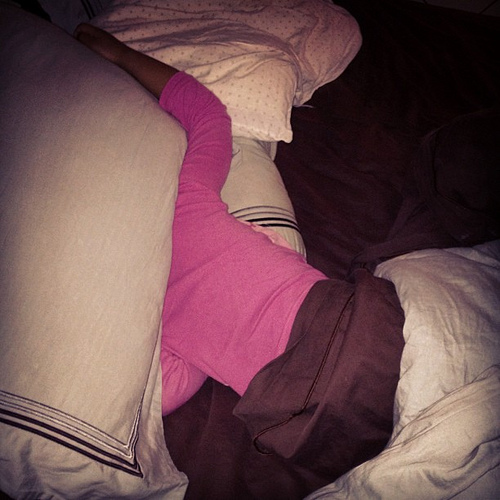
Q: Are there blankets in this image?
A: Yes, there is a blanket.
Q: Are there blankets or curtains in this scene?
A: Yes, there is a blanket.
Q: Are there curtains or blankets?
A: Yes, there is a blanket.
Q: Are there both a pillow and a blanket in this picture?
A: Yes, there are both a blanket and a pillow.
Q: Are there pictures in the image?
A: No, there are no pictures.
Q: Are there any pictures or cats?
A: No, there are no pictures or cats.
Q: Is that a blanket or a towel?
A: That is a blanket.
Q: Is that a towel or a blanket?
A: That is a blanket.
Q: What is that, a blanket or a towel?
A: That is a blanket.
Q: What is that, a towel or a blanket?
A: That is a blanket.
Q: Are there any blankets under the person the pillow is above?
A: Yes, there is a blanket under the person.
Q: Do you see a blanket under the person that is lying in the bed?
A: Yes, there is a blanket under the person.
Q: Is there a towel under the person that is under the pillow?
A: No, there is a blanket under the person.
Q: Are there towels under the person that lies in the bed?
A: No, there is a blanket under the person.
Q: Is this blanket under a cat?
A: No, the blanket is under a person.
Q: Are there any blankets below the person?
A: Yes, there is a blanket below the person.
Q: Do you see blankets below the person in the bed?
A: Yes, there is a blanket below the person.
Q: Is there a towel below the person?
A: No, there is a blanket below the person.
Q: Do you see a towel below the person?
A: No, there is a blanket below the person.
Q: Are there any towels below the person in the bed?
A: No, there is a blanket below the person.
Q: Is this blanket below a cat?
A: No, the blanket is below the person.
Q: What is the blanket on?
A: The blanket is on the bed.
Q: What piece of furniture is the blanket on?
A: The blanket is on the bed.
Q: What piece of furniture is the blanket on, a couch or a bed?
A: The blanket is on a bed.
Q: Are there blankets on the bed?
A: Yes, there is a blanket on the bed.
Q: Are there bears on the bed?
A: No, there is a blanket on the bed.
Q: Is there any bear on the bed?
A: No, there is a blanket on the bed.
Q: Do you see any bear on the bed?
A: No, there is a blanket on the bed.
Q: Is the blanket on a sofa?
A: No, the blanket is on a bed.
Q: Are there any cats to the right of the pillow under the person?
A: No, there is a blanket to the right of the pillow.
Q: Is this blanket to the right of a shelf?
A: No, the blanket is to the right of a pillow.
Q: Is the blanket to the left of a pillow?
A: No, the blanket is to the right of a pillow.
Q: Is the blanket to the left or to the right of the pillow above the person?
A: The blanket is to the right of the pillow.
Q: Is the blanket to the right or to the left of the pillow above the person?
A: The blanket is to the right of the pillow.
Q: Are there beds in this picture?
A: Yes, there is a bed.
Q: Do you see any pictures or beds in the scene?
A: Yes, there is a bed.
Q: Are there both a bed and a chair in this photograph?
A: No, there is a bed but no chairs.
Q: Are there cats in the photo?
A: No, there are no cats.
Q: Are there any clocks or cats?
A: No, there are no cats or clocks.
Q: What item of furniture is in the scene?
A: The piece of furniture is a bed.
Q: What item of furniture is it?
A: The piece of furniture is a bed.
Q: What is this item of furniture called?
A: This is a bed.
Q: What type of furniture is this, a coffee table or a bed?
A: This is a bed.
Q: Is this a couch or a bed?
A: This is a bed.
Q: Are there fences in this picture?
A: No, there are no fences.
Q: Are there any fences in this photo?
A: No, there are no fences.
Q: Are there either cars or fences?
A: No, there are no fences or cars.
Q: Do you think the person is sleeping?
A: Yes, the person is sleeping.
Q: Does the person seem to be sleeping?
A: Yes, the person is sleeping.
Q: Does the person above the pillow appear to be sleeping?
A: Yes, the person is sleeping.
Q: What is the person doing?
A: The person is sleeping.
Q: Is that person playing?
A: No, the person is sleeping.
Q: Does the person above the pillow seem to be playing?
A: No, the person is sleeping.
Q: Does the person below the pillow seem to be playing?
A: No, the person is sleeping.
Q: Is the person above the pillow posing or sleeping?
A: The person is sleeping.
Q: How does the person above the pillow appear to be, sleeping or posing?
A: The person is sleeping.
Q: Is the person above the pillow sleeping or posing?
A: The person is sleeping.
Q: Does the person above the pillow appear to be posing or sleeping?
A: The person is sleeping.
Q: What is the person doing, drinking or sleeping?
A: The person is sleeping.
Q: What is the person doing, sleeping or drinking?
A: The person is sleeping.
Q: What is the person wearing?
A: The person is wearing a shirt.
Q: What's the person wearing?
A: The person is wearing a shirt.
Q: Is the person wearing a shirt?
A: Yes, the person is wearing a shirt.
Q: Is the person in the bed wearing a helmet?
A: No, the person is wearing a shirt.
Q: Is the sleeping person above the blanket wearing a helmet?
A: No, the person is wearing a shirt.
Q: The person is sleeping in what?
A: The person is sleeping in the bed.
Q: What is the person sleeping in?
A: The person is sleeping in the bed.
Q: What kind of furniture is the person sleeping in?
A: The person is sleeping in the bed.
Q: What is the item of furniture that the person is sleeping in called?
A: The piece of furniture is a bed.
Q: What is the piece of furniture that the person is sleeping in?
A: The piece of furniture is a bed.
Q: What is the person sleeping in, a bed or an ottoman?
A: The person is sleeping in a bed.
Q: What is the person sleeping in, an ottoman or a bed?
A: The person is sleeping in a bed.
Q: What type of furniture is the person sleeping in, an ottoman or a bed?
A: The person is sleeping in a bed.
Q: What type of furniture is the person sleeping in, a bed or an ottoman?
A: The person is sleeping in a bed.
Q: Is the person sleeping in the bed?
A: Yes, the person is sleeping in the bed.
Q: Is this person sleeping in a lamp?
A: No, the person is sleeping in the bed.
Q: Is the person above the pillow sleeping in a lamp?
A: No, the person is sleeping in the bed.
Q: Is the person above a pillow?
A: Yes, the person is above a pillow.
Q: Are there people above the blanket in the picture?
A: Yes, there is a person above the blanket.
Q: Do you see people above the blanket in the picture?
A: Yes, there is a person above the blanket.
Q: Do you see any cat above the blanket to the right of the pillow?
A: No, there is a person above the blanket.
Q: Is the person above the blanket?
A: Yes, the person is above the blanket.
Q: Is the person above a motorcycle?
A: No, the person is above the blanket.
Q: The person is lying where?
A: The person is lying in the bed.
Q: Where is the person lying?
A: The person is lying in the bed.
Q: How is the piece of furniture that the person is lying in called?
A: The piece of furniture is a bed.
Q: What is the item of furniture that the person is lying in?
A: The piece of furniture is a bed.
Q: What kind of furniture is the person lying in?
A: The person is lying in the bed.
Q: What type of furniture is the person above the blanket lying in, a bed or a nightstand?
A: The person is lying in a bed.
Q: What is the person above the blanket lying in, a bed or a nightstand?
A: The person is lying in a bed.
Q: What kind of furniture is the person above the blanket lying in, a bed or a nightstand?
A: The person is lying in a bed.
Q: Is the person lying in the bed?
A: Yes, the person is lying in the bed.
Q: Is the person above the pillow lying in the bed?
A: Yes, the person is lying in the bed.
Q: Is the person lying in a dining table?
A: No, the person is lying in the bed.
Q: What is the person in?
A: The person is in the bed.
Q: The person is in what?
A: The person is in the bed.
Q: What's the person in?
A: The person is in the bed.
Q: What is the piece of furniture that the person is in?
A: The piece of furniture is a bed.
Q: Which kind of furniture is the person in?
A: The person is in the bed.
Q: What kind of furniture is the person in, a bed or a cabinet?
A: The person is in a bed.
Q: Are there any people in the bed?
A: Yes, there is a person in the bed.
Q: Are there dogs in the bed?
A: No, there is a person in the bed.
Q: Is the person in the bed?
A: Yes, the person is in the bed.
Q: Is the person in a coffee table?
A: No, the person is in the bed.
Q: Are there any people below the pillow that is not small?
A: Yes, there is a person below the pillow.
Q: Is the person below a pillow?
A: Yes, the person is below a pillow.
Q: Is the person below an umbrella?
A: No, the person is below a pillow.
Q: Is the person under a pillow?
A: Yes, the person is under a pillow.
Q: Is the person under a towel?
A: No, the person is under a pillow.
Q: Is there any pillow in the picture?
A: Yes, there is a pillow.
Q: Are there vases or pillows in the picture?
A: Yes, there is a pillow.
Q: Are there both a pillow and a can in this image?
A: No, there is a pillow but no cans.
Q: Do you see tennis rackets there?
A: No, there are no tennis rackets.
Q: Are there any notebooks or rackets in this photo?
A: No, there are no rackets or notebooks.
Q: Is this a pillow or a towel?
A: This is a pillow.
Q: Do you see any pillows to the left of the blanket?
A: Yes, there is a pillow to the left of the blanket.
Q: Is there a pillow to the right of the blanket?
A: No, the pillow is to the left of the blanket.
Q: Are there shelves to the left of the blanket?
A: No, there is a pillow to the left of the blanket.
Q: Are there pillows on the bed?
A: Yes, there is a pillow on the bed.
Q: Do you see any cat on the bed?
A: No, there is a pillow on the bed.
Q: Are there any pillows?
A: Yes, there is a pillow.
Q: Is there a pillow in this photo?
A: Yes, there is a pillow.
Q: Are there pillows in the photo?
A: Yes, there is a pillow.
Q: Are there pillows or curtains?
A: Yes, there is a pillow.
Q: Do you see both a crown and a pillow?
A: No, there is a pillow but no crowns.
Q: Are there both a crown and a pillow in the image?
A: No, there is a pillow but no crowns.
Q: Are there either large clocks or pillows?
A: Yes, there is a large pillow.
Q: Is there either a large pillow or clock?
A: Yes, there is a large pillow.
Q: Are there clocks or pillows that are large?
A: Yes, the pillow is large.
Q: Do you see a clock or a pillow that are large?
A: Yes, the pillow is large.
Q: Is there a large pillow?
A: Yes, there is a large pillow.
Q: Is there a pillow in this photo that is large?
A: Yes, there is a pillow that is large.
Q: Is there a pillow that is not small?
A: Yes, there is a large pillow.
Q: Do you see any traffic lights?
A: No, there are no traffic lights.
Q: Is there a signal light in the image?
A: No, there are no traffic lights.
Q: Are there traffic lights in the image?
A: No, there are no traffic lights.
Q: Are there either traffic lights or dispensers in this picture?
A: No, there are no traffic lights or dispensers.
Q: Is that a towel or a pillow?
A: That is a pillow.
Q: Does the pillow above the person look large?
A: Yes, the pillow is large.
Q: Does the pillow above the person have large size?
A: Yes, the pillow is large.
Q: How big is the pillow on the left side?
A: The pillow is large.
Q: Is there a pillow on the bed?
A: Yes, there is a pillow on the bed.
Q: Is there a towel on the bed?
A: No, there is a pillow on the bed.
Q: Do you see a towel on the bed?
A: No, there is a pillow on the bed.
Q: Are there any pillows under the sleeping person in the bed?
A: Yes, there is a pillow under the person.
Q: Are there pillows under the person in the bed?
A: Yes, there is a pillow under the person.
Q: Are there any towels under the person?
A: No, there is a pillow under the person.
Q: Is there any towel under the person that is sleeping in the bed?
A: No, there is a pillow under the person.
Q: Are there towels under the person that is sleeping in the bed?
A: No, there is a pillow under the person.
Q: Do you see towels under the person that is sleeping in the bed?
A: No, there is a pillow under the person.